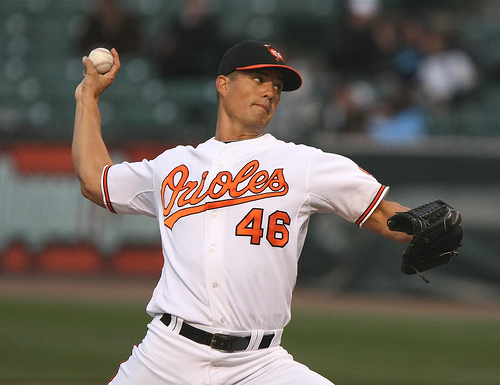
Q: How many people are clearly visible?
A: One.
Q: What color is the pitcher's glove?
A: Black.